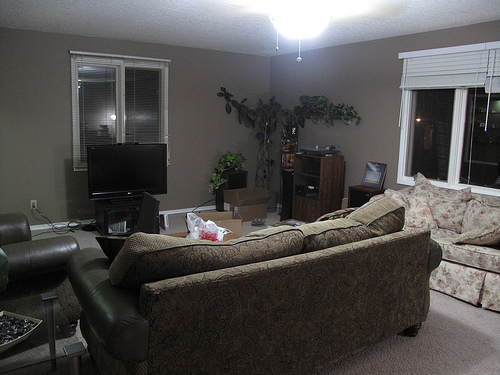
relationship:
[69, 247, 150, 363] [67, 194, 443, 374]
arm on sofa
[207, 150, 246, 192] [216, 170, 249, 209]
plant on speaker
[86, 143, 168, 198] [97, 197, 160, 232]
tv on entertainment center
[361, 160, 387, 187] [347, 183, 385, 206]
picture on speaker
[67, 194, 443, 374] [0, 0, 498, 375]
sofa in living room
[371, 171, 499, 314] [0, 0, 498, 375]
sofa in living room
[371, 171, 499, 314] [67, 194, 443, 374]
sofa to right of sofa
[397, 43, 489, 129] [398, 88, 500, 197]
blind on window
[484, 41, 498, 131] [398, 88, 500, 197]
blind on window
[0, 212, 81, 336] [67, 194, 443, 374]
chair next to sofa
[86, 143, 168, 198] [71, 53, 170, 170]
tv in front of window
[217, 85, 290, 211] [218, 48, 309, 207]
plant in corner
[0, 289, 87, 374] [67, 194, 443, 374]
table next to sofa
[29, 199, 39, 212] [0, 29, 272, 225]
outlet on wall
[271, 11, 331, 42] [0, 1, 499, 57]
light on ceiling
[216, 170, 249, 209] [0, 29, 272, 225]
speaker against wall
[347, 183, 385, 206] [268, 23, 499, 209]
speaker against wall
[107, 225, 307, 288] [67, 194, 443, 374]
cushion on sofa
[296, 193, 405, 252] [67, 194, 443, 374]
cushion on sofa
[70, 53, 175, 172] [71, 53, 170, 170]
frame around window